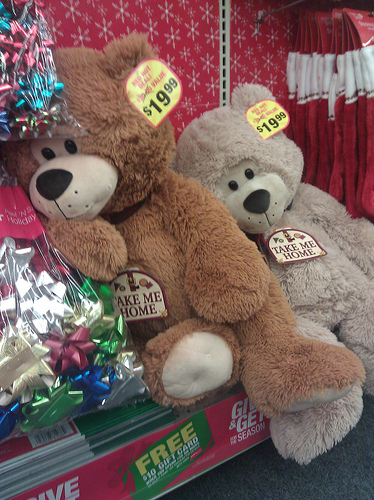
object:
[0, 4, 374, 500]
store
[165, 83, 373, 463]
teddy bear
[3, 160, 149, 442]
plastic bag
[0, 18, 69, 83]
bows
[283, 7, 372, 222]
stockings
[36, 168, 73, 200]
nose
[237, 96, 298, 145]
tag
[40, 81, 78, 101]
eyes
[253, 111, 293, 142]
19.99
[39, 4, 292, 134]
snowflake pattern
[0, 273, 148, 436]
gift bow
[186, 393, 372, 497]
floor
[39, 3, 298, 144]
paper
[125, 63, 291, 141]
two tags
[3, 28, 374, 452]
two bags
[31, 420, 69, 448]
bar code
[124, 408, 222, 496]
sticker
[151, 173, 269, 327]
arm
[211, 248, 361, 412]
leg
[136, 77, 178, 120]
price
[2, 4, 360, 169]
wall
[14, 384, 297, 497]
ledge